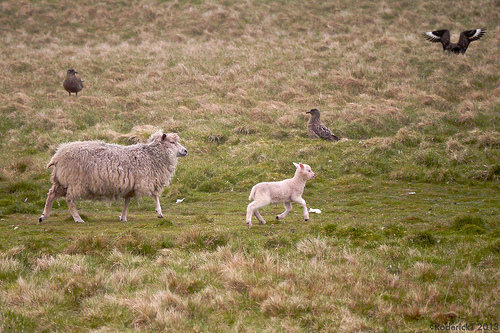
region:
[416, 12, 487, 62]
bird with it's wings extended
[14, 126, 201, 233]
full grown sheep walking in the field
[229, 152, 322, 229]
lamb running ahead of the sheep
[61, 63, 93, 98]
bird standing in the grass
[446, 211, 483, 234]
weeds growing in the grass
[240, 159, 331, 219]
lamb in the field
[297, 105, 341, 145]
bird in the dead grass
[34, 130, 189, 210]
sheep with lots of wool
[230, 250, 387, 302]
dead grass in the field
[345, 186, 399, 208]
green grass in the field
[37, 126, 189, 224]
An adult goat walking on a field.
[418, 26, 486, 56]
A hawk in mid flight.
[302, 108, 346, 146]
A prairie bird looking around.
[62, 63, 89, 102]
A yard bird looking for food.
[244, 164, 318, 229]
A baby sheep prancing around.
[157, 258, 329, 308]
Dry grass dying in the sun.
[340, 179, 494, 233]
Green thickets of grass.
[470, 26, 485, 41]
A white marking on a black hawk.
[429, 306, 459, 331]
A chunk of sheep dung.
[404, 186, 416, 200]
A patch of animal fur laying in the grass.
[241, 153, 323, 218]
lamp running through the grass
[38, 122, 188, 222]
sheep walking through grass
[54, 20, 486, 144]
three birds in the grass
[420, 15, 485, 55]
bird with his wings spread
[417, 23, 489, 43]
white stripes on bird's wings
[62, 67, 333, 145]
two birds standing in the grass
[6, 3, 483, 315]
grass pasture sheep and birds are in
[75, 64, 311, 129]
beaks of two birds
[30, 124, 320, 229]
lamp and sheep traveling together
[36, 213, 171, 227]
hooves of the sheep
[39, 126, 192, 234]
the sheep wlaking on the grass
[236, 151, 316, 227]
the lamb running in the field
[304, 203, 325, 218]
the white trash on the ground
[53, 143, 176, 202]
the fur of the sheep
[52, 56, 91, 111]
the bird standing in the field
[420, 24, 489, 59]
the bird flying in the air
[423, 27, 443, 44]
the white marking on the wing of the bird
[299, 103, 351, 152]
the bird standing in the grass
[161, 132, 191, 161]
the face of the sheep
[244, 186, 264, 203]
the white tail of the lamb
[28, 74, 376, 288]
sheep walking in field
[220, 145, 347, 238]
small baby sheep in field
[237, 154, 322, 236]
small baby sheep in grass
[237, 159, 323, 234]
furry white small sheep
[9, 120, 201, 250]
large furry adult sheep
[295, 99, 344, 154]
small bird standing in field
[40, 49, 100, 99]
bird standing in field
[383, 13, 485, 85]
bird flapping its wings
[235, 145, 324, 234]
small sheep walking on grass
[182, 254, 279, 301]
tufts of brown and green grass